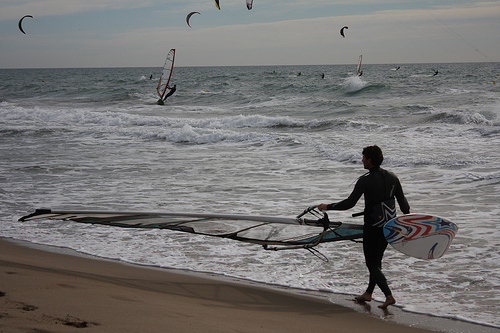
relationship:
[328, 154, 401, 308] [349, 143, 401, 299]
person wears wetsuit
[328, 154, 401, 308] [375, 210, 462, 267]
person carrying board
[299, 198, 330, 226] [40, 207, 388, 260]
handle on sail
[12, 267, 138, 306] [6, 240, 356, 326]
footprints on beach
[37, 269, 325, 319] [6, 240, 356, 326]
shadow on beach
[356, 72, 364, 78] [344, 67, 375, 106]
person on wave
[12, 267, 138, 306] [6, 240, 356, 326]
footprints in beach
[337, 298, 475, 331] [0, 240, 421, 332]
water on beach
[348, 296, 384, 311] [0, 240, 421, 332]
feet in beach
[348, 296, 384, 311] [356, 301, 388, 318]
feet cast shadow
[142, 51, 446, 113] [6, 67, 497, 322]
people in ocean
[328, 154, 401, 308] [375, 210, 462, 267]
person carries board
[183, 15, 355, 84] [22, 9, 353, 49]
strings on kites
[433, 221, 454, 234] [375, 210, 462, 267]
star on board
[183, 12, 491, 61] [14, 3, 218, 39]
clouds in sky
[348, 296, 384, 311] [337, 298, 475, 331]
feet near water